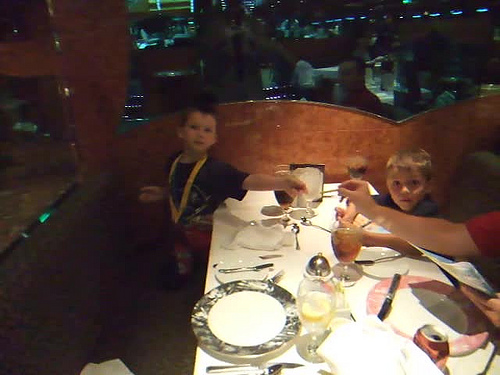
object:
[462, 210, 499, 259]
sleeve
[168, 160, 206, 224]
lanyard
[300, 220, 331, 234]
spoon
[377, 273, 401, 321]
knife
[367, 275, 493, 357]
plate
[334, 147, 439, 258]
boy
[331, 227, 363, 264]
glass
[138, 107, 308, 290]
boy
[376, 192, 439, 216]
shirt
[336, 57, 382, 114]
man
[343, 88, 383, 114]
shirt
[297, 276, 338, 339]
glass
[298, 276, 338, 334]
wine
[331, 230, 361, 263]
tea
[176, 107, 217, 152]
head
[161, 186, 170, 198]
arm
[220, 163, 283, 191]
arm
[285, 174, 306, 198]
hand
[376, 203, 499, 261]
arm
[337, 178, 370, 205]
hand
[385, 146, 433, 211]
head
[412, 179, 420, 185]
eye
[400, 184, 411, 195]
nose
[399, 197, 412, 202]
mouth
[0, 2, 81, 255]
mirror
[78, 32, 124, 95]
wall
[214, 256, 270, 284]
plate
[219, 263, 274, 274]
knife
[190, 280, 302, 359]
plate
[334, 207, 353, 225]
hands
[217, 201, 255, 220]
table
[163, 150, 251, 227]
shirt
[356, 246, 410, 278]
plate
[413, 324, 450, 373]
can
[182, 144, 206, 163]
neck